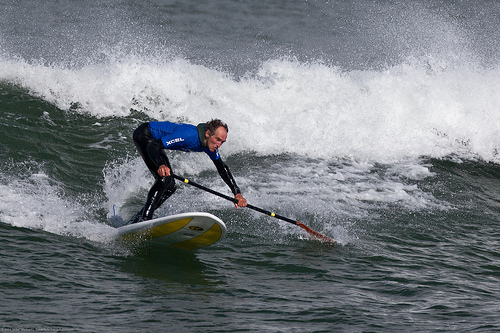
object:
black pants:
[136, 136, 172, 215]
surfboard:
[111, 211, 228, 252]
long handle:
[167, 171, 240, 204]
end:
[292, 217, 343, 243]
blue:
[153, 119, 202, 145]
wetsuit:
[132, 118, 239, 216]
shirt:
[147, 120, 222, 161]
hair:
[199, 117, 229, 133]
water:
[368, 202, 493, 243]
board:
[115, 212, 227, 250]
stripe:
[122, 211, 220, 248]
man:
[129, 117, 247, 227]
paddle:
[173, 173, 343, 245]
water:
[247, 279, 497, 330]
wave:
[1, 39, 497, 166]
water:
[1, 2, 153, 73]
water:
[299, 151, 436, 219]